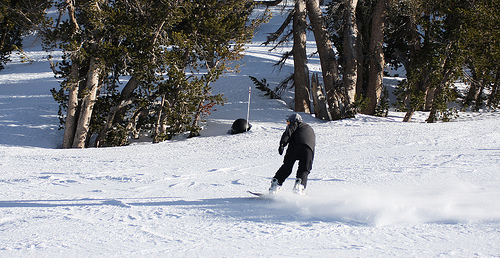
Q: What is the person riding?
A: Snowboard.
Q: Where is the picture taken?
A: Ski slope.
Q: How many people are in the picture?
A: One.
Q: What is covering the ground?
A: Snow.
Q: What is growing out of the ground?
A: Trees.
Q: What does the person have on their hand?
A: Glove.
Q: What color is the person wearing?
A: Black.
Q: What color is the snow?
A: White.